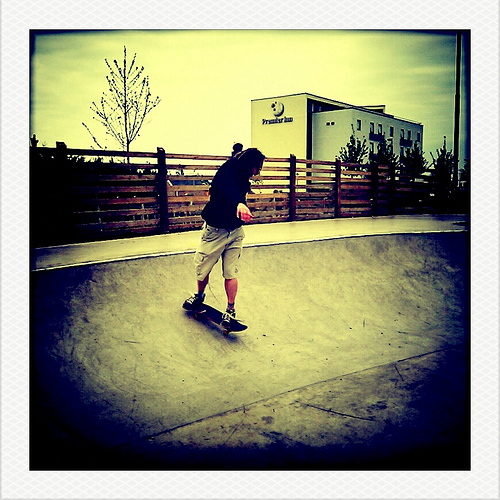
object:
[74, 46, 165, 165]
tree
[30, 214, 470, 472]
ground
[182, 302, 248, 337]
skateboard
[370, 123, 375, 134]
window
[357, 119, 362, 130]
window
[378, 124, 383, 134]
window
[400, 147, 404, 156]
window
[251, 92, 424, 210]
building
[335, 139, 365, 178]
tree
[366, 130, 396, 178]
tree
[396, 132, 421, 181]
tree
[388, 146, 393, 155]
window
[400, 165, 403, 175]
window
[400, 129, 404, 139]
window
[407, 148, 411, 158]
window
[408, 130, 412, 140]
window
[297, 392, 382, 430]
mark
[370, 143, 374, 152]
window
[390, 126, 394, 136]
window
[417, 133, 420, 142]
window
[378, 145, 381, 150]
window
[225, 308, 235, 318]
shoes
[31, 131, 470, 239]
fence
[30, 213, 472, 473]
park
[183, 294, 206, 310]
feet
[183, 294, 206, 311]
shoes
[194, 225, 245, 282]
shorts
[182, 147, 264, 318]
man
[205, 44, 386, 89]
sky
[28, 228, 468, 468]
ramp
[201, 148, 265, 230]
hoodie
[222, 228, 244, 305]
legs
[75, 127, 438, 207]
background